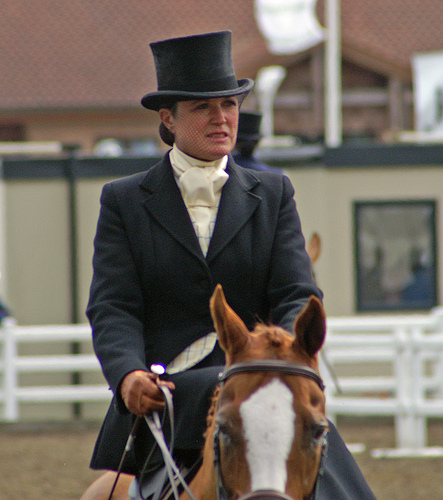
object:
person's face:
[175, 95, 241, 154]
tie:
[166, 142, 230, 206]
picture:
[352, 198, 437, 311]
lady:
[87, 26, 377, 500]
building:
[0, 140, 443, 423]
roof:
[1, 0, 443, 113]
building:
[0, 0, 443, 161]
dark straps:
[219, 361, 326, 388]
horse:
[77, 286, 330, 500]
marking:
[239, 374, 296, 496]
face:
[212, 326, 327, 500]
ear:
[291, 292, 328, 358]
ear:
[208, 282, 252, 360]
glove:
[117, 367, 177, 419]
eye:
[218, 97, 238, 108]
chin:
[198, 139, 233, 157]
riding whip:
[108, 362, 168, 500]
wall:
[282, 161, 443, 399]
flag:
[252, 0, 328, 55]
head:
[159, 95, 239, 158]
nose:
[209, 105, 228, 125]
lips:
[206, 137, 228, 144]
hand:
[118, 368, 173, 418]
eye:
[216, 420, 229, 436]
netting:
[155, 99, 240, 159]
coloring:
[238, 376, 298, 494]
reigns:
[140, 384, 195, 500]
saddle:
[125, 456, 201, 500]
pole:
[320, 0, 344, 149]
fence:
[0, 314, 443, 460]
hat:
[138, 30, 253, 110]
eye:
[311, 421, 328, 442]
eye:
[190, 102, 211, 111]